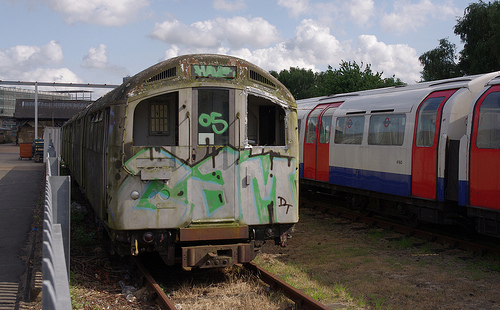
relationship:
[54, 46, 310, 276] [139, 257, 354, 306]
train on track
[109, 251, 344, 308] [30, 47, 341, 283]
track under train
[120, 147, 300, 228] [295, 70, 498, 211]
paint on front of train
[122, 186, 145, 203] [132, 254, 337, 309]
light hitting track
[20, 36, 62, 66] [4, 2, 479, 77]
cloud in sky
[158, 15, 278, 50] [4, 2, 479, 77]
cloud in sky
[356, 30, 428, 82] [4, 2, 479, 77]
cloud in sky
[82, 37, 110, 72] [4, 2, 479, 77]
cloud in sky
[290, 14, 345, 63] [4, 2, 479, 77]
cloud in sky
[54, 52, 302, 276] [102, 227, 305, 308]
train on tracks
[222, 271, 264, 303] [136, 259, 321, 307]
grass growing on track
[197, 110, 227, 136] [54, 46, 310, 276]
green lettering on train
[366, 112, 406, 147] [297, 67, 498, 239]
window on train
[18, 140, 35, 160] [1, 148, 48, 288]
container on ground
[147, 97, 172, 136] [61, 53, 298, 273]
window on train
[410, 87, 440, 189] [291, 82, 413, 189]
door in train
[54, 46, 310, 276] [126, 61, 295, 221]
train has writtings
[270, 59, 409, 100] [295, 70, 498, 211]
tree growing next to train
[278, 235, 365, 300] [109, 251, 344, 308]
grass between track